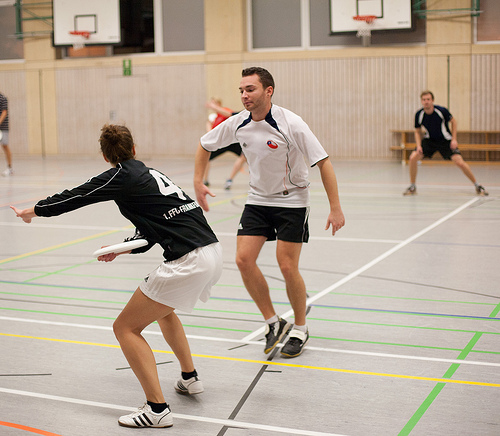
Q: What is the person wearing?
A: Shorts.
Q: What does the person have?
A: Frisbee.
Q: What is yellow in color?
A: The line.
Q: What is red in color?
A: Rim.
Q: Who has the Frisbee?
A: A girl.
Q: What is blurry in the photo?
A: The background.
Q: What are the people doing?
A: Playing frisbee.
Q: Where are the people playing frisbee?
A: On a basketball court.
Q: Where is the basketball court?
A: Inside a building.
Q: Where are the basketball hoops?
A: On the wall.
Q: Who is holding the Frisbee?
A: A woman.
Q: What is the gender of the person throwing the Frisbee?
A: Female.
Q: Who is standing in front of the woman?
A: A man.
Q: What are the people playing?
A: Frisbee.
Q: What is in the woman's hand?
A: Frisbee.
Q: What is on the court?
A: Lines.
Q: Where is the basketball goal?
A: Hanging from wall.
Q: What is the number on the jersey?
A: 4.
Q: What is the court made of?
A: Concrete.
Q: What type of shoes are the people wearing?
A: Sneakers.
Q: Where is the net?
A: Rim.